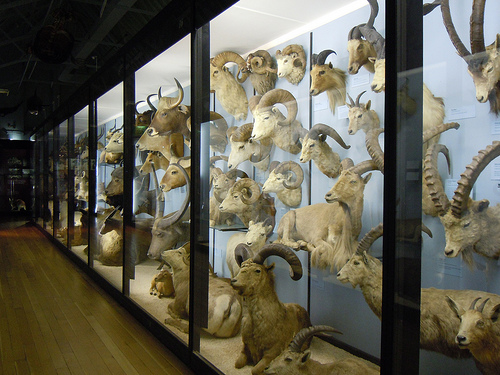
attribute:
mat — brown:
[0, 221, 230, 374]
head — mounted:
[211, 51, 248, 115]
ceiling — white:
[46, 16, 151, 91]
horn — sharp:
[390, 109, 498, 202]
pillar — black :
[380, 2, 427, 374]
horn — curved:
[251, 241, 303, 285]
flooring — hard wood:
[3, 220, 208, 374]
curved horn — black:
[308, 49, 321, 68]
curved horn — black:
[319, 45, 337, 66]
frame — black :
[184, 27, 206, 362]